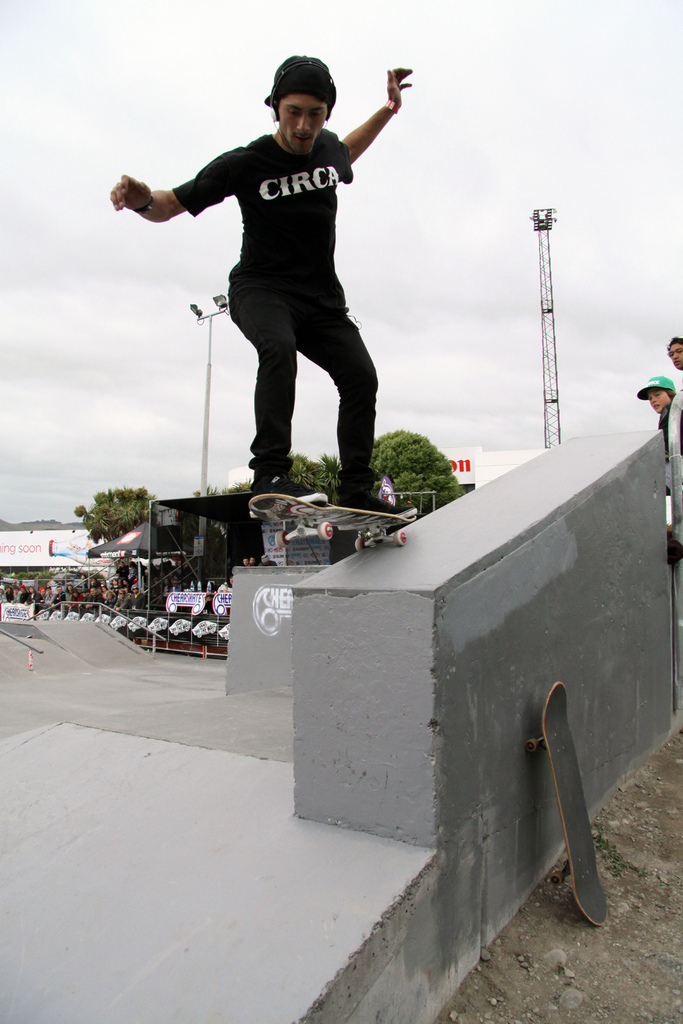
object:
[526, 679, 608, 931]
skateboard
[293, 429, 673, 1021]
wall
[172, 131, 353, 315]
shirt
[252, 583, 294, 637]
letters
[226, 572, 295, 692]
wall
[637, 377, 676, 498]
person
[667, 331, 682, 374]
hair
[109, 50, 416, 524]
person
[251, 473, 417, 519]
tennis shoes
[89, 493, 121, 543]
leaves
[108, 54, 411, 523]
guy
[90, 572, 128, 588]
spectators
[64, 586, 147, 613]
stand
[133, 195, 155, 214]
watch band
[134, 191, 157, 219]
wrist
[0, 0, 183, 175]
clouds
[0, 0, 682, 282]
sky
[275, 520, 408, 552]
wheels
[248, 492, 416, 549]
skateboard